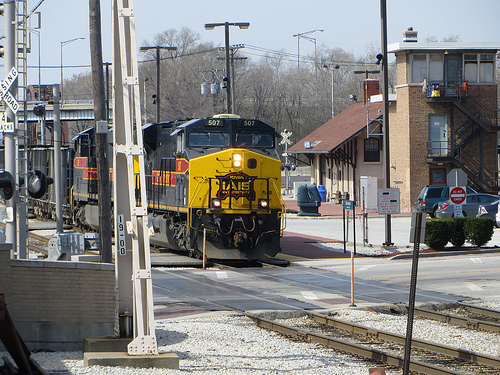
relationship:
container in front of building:
[315, 181, 325, 201] [281, 24, 493, 214]